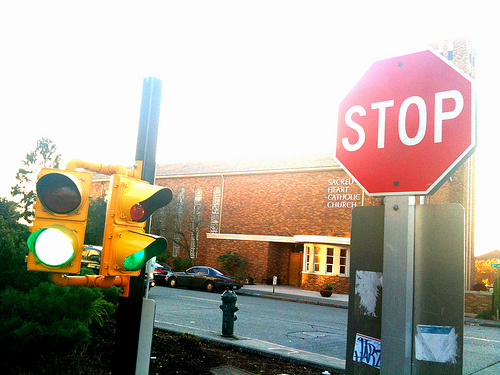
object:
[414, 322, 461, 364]
paper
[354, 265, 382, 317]
paper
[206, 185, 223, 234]
window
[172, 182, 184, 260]
window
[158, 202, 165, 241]
window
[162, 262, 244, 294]
car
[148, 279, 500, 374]
road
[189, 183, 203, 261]
window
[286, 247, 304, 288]
doorway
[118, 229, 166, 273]
traffic signal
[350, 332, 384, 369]
graffiti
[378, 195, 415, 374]
post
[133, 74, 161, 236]
pole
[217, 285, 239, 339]
fire hydrant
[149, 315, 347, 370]
sidewalk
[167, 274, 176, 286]
vehicle/front wheel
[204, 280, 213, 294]
vehicle/rear wheel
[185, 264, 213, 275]
vehicle/side windows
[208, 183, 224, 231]
building window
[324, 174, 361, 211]
lettering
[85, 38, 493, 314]
building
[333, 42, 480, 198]
red/stop sign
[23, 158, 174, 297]
lights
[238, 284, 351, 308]
curb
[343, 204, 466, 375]
sign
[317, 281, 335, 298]
planter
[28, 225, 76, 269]
green/traffic light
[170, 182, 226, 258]
three/church windows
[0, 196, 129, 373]
bushes